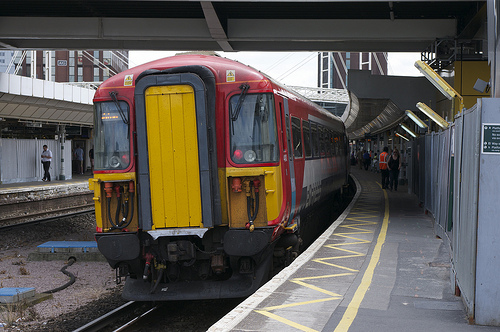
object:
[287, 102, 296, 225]
doors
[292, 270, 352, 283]
lines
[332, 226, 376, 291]
line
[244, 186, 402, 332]
line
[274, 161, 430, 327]
ground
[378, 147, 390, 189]
man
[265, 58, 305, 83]
sky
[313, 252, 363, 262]
line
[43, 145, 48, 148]
dark hair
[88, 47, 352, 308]
train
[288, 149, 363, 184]
trim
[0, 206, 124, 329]
ground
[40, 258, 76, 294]
hose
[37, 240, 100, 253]
box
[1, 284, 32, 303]
box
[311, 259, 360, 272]
lines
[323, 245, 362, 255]
yellow/painted line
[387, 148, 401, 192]
person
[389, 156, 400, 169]
black shirt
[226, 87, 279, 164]
window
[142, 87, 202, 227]
door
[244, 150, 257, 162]
light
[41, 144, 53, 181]
man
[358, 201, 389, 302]
line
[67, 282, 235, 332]
track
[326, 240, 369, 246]
line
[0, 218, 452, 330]
ground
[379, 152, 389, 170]
orange vest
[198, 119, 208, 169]
lining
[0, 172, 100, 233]
platform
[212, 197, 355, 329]
white line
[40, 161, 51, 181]
pants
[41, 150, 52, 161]
shirt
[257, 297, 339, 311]
line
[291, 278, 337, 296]
line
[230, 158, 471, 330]
platform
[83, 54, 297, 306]
back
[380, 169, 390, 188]
pants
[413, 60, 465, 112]
light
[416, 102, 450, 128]
light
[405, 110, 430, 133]
light